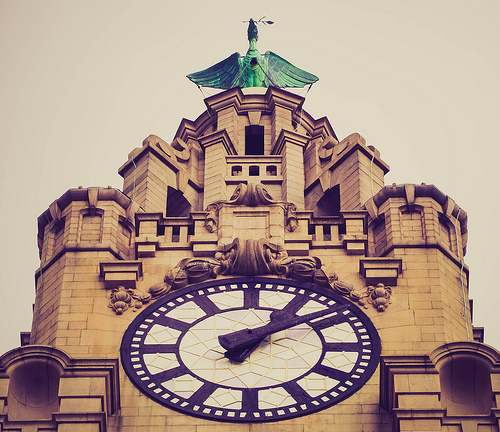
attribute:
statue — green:
[187, 19, 324, 94]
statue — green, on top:
[192, 19, 311, 89]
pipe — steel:
[450, 202, 475, 339]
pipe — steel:
[28, 211, 50, 343]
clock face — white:
[131, 281, 373, 416]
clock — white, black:
[95, 280, 400, 417]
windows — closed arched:
[106, 212, 383, 243]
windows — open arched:
[224, 121, 280, 183]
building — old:
[21, 39, 493, 391]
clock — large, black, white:
[114, 269, 381, 421]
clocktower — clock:
[30, 101, 488, 407]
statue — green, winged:
[185, 15, 321, 92]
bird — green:
[184, 12, 321, 91]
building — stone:
[79, 175, 429, 427]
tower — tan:
[0, 85, 496, 429]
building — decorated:
[2, 8, 499, 430]